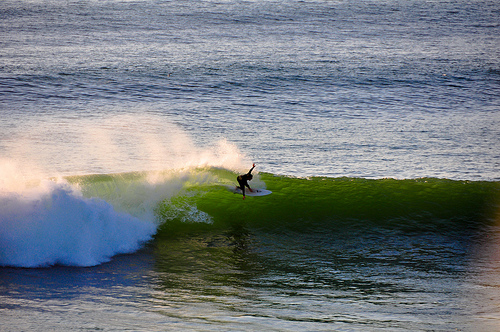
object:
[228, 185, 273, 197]
board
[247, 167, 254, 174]
arm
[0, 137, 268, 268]
wave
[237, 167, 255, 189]
wetsuit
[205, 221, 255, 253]
shadow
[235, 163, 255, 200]
person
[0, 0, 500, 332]
ocean